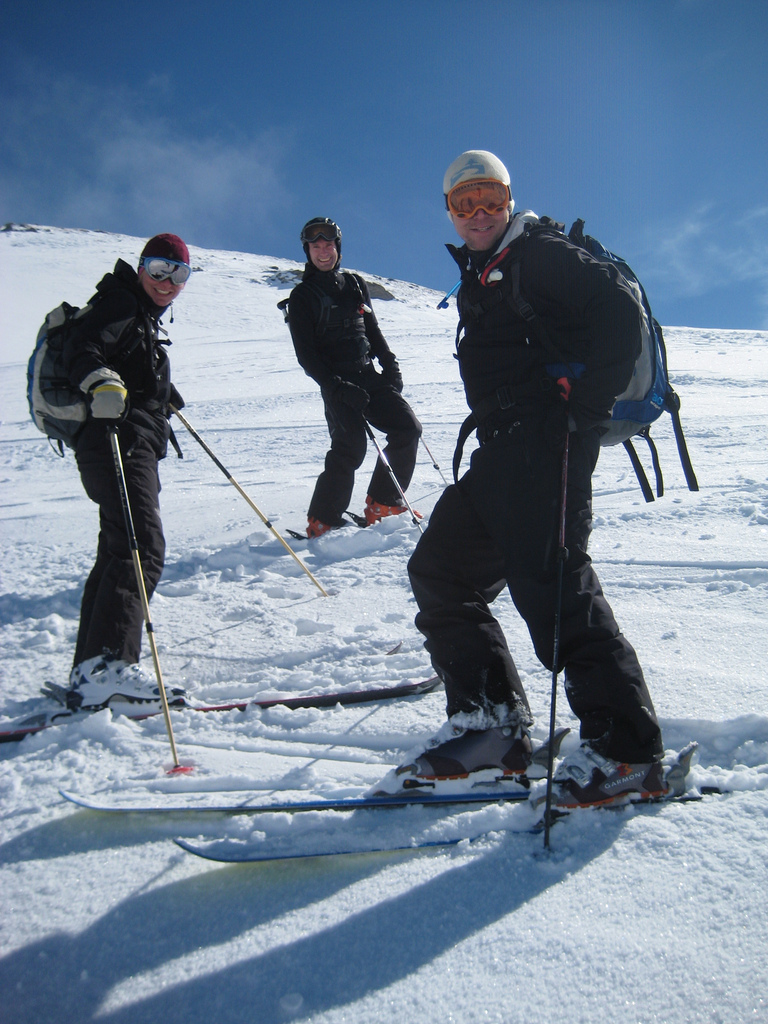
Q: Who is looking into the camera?
A: Men.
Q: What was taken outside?
A: This photo.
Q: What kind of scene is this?
A: A daytime scene.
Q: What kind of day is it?
A: Bright.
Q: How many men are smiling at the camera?
A: Three.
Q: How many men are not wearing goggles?
A: One.